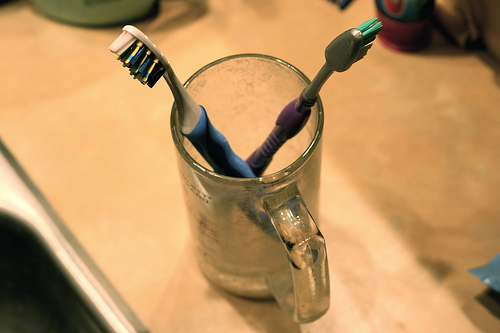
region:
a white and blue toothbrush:
[109, 23, 252, 180]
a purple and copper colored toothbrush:
[247, 14, 378, 176]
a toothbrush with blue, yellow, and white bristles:
[108, 25, 255, 182]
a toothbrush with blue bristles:
[247, 18, 384, 172]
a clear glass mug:
[169, 49, 329, 321]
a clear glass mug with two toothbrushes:
[110, 16, 381, 324]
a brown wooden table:
[11, 1, 494, 328]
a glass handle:
[263, 196, 332, 321]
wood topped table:
[0, 1, 499, 331]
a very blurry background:
[0, 0, 497, 329]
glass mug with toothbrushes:
[172, 74, 338, 281]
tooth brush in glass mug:
[129, 28, 276, 163]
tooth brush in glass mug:
[298, 24, 403, 139]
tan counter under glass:
[77, 54, 497, 331]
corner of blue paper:
[457, 236, 497, 288]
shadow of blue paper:
[444, 269, 494, 309]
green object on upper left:
[49, 4, 116, 39]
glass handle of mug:
[259, 165, 369, 322]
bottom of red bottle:
[377, 10, 457, 79]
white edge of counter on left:
[17, 195, 159, 325]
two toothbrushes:
[114, 8, 406, 241]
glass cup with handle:
[171, 53, 354, 315]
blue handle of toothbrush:
[192, 107, 254, 187]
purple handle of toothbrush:
[246, 94, 316, 181]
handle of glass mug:
[263, 188, 325, 332]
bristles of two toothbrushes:
[112, 20, 388, 91]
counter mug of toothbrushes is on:
[11, 15, 485, 332]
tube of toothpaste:
[366, 4, 443, 54]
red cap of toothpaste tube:
[365, 8, 427, 53]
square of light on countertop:
[34, 55, 488, 330]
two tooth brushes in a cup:
[114, 16, 384, 324]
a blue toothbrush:
[105, 24, 253, 183]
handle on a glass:
[261, 192, 331, 324]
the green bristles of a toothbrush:
[356, 18, 379, 68]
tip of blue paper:
[468, 254, 498, 293]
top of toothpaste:
[376, 1, 437, 49]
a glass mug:
[167, 53, 330, 323]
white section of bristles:
[110, 32, 133, 54]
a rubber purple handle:
[245, 100, 305, 171]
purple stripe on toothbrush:
[269, 132, 280, 142]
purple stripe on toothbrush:
[266, 133, 278, 147]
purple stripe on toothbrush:
[263, 138, 273, 148]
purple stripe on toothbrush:
[261, 143, 271, 150]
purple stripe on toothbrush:
[257, 143, 267, 156]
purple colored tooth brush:
[247, 15, 382, 173]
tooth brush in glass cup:
[240, 12, 380, 172]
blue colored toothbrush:
[106, 17, 288, 237]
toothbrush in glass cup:
[107, 22, 300, 252]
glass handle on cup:
[259, 196, 335, 322]